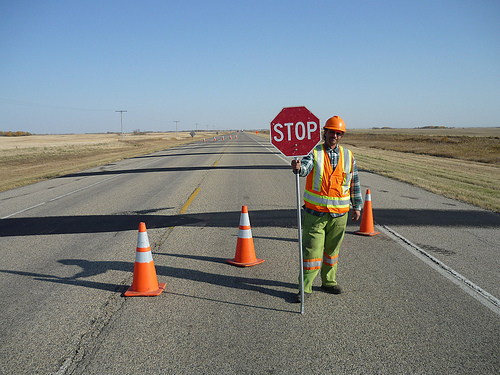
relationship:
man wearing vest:
[269, 106, 364, 314] [307, 143, 355, 213]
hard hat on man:
[323, 116, 346, 133] [269, 106, 364, 314]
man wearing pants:
[269, 106, 364, 314] [295, 194, 346, 292]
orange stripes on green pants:
[303, 258, 322, 270] [298, 207, 347, 294]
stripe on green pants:
[324, 253, 343, 259] [298, 207, 347, 294]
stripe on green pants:
[323, 252, 338, 266] [298, 207, 347, 294]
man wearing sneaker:
[269, 106, 364, 314] [292, 289, 314, 303]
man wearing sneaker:
[269, 106, 364, 314] [317, 281, 341, 294]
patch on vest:
[311, 147, 325, 191] [301, 139, 355, 216]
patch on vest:
[341, 148, 351, 201] [301, 139, 355, 216]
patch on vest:
[303, 190, 354, 206] [301, 139, 355, 216]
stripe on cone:
[133, 250, 153, 264] [119, 218, 167, 297]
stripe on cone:
[137, 231, 150, 248] [119, 218, 167, 297]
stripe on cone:
[233, 227, 256, 239] [222, 201, 265, 267]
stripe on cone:
[237, 210, 253, 230] [222, 201, 265, 267]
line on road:
[173, 141, 228, 220] [1, 130, 498, 372]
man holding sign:
[269, 106, 364, 314] [270, 108, 322, 310]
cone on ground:
[124, 221, 167, 296] [0, 126, 500, 375]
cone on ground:
[226, 205, 265, 267] [0, 126, 500, 375]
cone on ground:
[354, 189, 380, 236] [0, 126, 500, 375]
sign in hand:
[244, 102, 334, 162] [292, 152, 302, 171]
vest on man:
[313, 160, 350, 207] [297, 102, 359, 295]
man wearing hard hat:
[269, 106, 364, 314] [323, 116, 346, 133]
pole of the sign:
[299, 192, 303, 306] [272, 107, 329, 302]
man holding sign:
[269, 106, 364, 314] [259, 99, 327, 310]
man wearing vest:
[269, 106, 364, 314] [312, 151, 352, 217]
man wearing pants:
[269, 106, 364, 314] [300, 206, 343, 285]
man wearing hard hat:
[323, 110, 351, 288] [323, 116, 346, 133]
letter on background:
[274, 121, 317, 142] [286, 105, 295, 110]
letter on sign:
[274, 121, 317, 142] [258, 96, 317, 166]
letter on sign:
[274, 121, 317, 142] [270, 108, 322, 310]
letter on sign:
[274, 121, 317, 142] [261, 100, 316, 162]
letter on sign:
[273, 120, 314, 134] [268, 102, 319, 160]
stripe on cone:
[137, 231, 154, 246] [125, 211, 162, 297]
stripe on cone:
[137, 231, 150, 248] [126, 223, 173, 305]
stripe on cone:
[137, 231, 150, 248] [106, 211, 170, 306]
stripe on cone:
[137, 231, 150, 248] [120, 210, 176, 303]